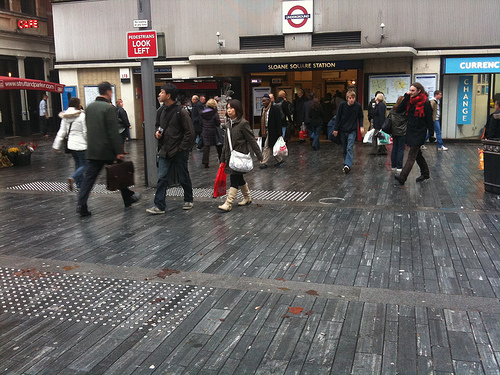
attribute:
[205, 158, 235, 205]
bag — red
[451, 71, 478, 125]
sign — blue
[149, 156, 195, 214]
pants — black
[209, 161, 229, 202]
bag — red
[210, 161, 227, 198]
bag — red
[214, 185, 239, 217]
boots — white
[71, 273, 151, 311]
dots — gray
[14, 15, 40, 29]
sign — red, cafe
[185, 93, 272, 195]
sign — red, white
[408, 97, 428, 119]
scarf — red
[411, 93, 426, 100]
neck — person's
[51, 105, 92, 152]
jacket — white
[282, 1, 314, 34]
sign — white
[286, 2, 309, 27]
circle — red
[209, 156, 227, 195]
bag — red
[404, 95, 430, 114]
scarf — red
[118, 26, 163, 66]
sign — red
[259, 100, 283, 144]
jacket — dark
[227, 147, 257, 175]
pocketbook — white